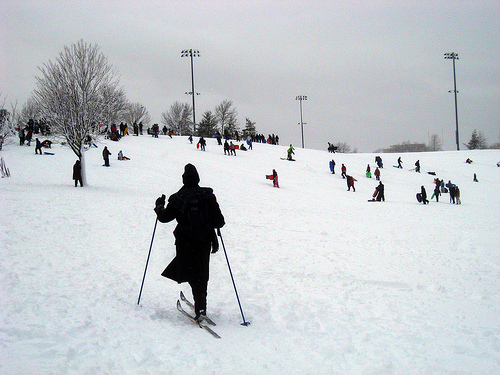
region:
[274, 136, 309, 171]
Person sking down slop of hill.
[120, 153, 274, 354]
Person walking on skis over snow.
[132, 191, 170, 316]
Person holding ski pole in hand.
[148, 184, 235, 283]
Skier dressed in long black coat.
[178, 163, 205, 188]
Skier wearing black wool cap on head.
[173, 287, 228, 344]
Skis attached to skier's feet.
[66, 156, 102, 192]
Person leaning against snow covered tree.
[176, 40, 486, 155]
Lamp post mounted on top of snow covered hill.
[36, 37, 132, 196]
Bare snow covered tree growing on top of hill.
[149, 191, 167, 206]
Skier wearing black glove on hand.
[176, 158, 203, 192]
the head of a person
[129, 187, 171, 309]
a black ski pole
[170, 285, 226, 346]
a pair of skis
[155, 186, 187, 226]
the arm of a person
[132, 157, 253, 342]
a person on the snow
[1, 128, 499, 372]
white snow on the ground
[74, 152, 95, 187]
the trunk of a tree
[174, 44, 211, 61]
lights on a pole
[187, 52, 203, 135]
a metal light post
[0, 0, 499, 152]
a gray sky overhead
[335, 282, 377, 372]
the snow is white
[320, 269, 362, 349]
the snow is white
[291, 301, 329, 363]
the snow is white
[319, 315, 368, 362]
the snow is white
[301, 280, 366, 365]
the snow is white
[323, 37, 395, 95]
this is the sky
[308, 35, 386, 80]
the sky is full of clouds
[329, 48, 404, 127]
the clouds are white in color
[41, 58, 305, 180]
these are some trees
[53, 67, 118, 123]
the trees have leaves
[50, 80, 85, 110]
the leaves are covered with snow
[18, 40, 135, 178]
the tree is short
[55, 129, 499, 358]
these are several people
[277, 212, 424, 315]
this is the snow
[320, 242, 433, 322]
the snow is white in color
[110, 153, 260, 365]
skier on snowy mountain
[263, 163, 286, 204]
skier on snowy mountain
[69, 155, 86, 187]
skier on snowy mountain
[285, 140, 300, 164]
skier on snowy mountain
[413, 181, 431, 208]
skier on snowy mountain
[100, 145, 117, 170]
skier on snowy mountain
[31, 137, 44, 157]
skier on snowy mountain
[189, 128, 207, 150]
skier on snowy mountain